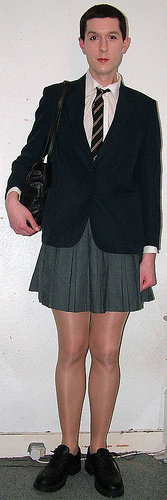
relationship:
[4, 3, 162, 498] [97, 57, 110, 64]
man wearing lipstick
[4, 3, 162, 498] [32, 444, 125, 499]
man wearing shoes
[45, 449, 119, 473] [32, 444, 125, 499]
shoe strings are on shoes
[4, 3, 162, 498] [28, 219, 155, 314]
man wearing skirt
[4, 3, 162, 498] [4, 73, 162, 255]
man wearing jacket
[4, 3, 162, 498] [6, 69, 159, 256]
man wearing shirt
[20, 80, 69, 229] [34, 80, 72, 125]
purse hanging on shoulder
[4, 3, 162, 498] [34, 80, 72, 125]
man has shoulder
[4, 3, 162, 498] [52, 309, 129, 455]
man wearing stockings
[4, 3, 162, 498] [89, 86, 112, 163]
man wearing tie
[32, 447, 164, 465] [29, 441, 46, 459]
something plugged into outlet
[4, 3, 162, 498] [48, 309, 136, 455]
man has legs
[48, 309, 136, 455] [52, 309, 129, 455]
legs are in stockings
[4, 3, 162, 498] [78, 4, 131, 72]
man has face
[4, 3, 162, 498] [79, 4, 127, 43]
man has hair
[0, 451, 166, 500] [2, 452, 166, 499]
carpet on floor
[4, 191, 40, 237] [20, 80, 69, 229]
hand beneath purse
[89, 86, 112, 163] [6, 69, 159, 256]
tie in front of shirt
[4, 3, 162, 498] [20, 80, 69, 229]
man carrying purse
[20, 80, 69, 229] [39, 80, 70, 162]
purse has straps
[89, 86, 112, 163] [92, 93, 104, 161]
tie has stripes